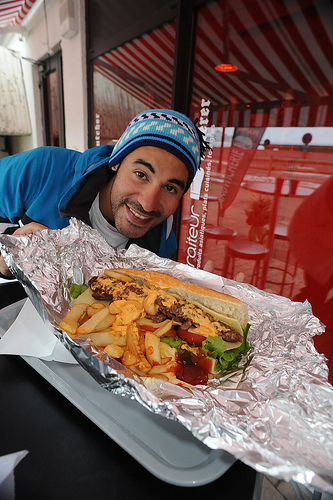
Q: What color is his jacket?
A: Blue.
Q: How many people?
A: One.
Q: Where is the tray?
A: Under the sandwich.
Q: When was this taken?
A: Day time.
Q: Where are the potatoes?
A: Next to sandwich.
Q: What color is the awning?
A: Red and white.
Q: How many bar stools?
A: Three.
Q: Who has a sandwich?
A: The man.